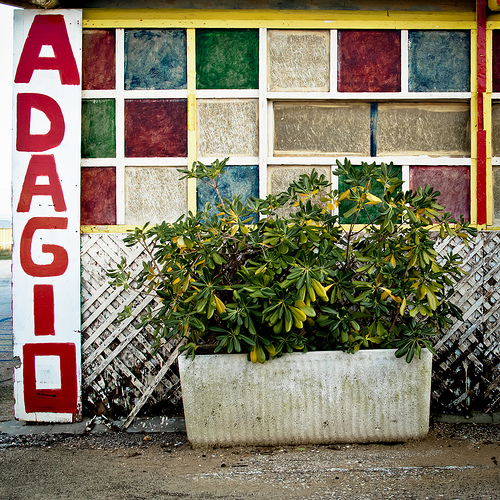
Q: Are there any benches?
A: No, there are no benches.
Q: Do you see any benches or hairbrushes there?
A: No, there are no benches or hairbrushes.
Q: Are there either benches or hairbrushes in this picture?
A: No, there are no benches or hairbrushes.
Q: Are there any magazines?
A: No, there are no magazines.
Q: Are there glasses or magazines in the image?
A: No, there are no magazines or glasses.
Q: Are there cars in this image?
A: No, there are no cars.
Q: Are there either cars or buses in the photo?
A: No, there are no cars or buses.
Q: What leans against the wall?
A: The sign leans against the wall.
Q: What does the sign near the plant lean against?
A: The sign leans against the wall.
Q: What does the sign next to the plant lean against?
A: The sign leans against the wall.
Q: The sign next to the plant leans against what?
A: The sign leans against the wall.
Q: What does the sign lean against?
A: The sign leans against the wall.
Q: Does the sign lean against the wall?
A: Yes, the sign leans against the wall.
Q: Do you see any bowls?
A: No, there are no bowls.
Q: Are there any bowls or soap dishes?
A: No, there are no bowls or soap dishes.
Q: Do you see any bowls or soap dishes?
A: No, there are no bowls or soap dishes.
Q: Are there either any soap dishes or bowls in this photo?
A: No, there are no bowls or soap dishes.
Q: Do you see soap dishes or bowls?
A: No, there are no bowls or soap dishes.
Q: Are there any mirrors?
A: No, there are no mirrors.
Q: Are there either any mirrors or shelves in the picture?
A: No, there are no mirrors or shelves.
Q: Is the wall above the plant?
A: Yes, the wall is above the plant.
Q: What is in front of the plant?
A: The ground is in front of the plant.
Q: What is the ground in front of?
A: The ground is in front of the plant.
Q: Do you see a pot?
A: Yes, there is a pot.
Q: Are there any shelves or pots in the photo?
A: Yes, there is a pot.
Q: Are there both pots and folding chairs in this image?
A: No, there is a pot but no folding chairs.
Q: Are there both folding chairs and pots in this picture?
A: No, there is a pot but no folding chairs.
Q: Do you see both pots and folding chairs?
A: No, there is a pot but no folding chairs.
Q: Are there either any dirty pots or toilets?
A: Yes, there is a dirty pot.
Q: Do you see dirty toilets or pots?
A: Yes, there is a dirty pot.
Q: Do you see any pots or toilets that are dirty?
A: Yes, the pot is dirty.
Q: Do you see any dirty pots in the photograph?
A: Yes, there is a dirty pot.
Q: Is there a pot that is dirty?
A: Yes, there is a pot that is dirty.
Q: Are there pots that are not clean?
A: Yes, there is a dirty pot.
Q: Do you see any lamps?
A: No, there are no lamps.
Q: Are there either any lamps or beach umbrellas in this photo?
A: No, there are no lamps or beach umbrellas.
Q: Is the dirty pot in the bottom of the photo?
A: Yes, the pot is in the bottom of the image.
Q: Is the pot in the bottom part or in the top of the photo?
A: The pot is in the bottom of the image.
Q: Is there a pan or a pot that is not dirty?
A: No, there is a pot but it is dirty.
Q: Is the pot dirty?
A: Yes, the pot is dirty.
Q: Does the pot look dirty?
A: Yes, the pot is dirty.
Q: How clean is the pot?
A: The pot is dirty.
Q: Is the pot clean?
A: No, the pot is dirty.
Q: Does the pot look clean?
A: No, the pot is dirty.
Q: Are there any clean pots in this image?
A: No, there is a pot but it is dirty.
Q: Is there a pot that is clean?
A: No, there is a pot but it is dirty.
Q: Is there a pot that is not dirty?
A: No, there is a pot but it is dirty.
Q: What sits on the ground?
A: The pot sits on the ground.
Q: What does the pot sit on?
A: The pot sits on the ground.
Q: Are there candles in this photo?
A: No, there are no candles.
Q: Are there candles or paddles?
A: No, there are no candles or paddles.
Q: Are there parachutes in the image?
A: No, there are no parachutes.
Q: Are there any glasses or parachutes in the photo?
A: No, there are no parachutes or glasses.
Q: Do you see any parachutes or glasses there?
A: No, there are no parachutes or glasses.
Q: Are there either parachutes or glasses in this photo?
A: No, there are no parachutes or glasses.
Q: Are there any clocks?
A: No, there are no clocks.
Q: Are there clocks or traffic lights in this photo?
A: No, there are no clocks or traffic lights.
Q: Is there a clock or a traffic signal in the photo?
A: No, there are no clocks or traffic lights.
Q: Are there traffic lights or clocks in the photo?
A: No, there are no clocks or traffic lights.